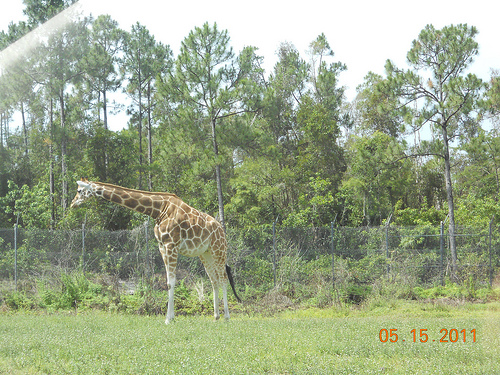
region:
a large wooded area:
[0, 0, 498, 284]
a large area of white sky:
[0, 0, 498, 170]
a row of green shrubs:
[0, 268, 498, 314]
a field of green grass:
[0, 303, 499, 373]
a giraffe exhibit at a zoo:
[0, 0, 499, 374]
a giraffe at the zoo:
[70, 175, 242, 323]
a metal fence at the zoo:
[0, 211, 499, 294]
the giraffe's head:
[70, 175, 95, 208]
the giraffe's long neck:
[92, 180, 170, 219]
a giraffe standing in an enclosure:
[70, 176, 242, 326]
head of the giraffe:
[68, 176, 93, 210]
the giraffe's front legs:
[153, 235, 180, 327]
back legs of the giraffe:
[212, 237, 232, 320]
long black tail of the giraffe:
[222, 254, 248, 304]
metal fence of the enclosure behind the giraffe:
[2, 225, 497, 287]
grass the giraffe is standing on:
[2, 307, 497, 371]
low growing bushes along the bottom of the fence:
[2, 273, 497, 312]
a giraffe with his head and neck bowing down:
[70, 176, 241, 324]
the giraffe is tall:
[77, 137, 334, 344]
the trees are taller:
[150, 14, 485, 281]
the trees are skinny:
[150, 67, 240, 199]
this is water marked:
[325, 307, 460, 374]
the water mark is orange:
[355, 294, 483, 362]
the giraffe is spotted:
[94, 173, 248, 304]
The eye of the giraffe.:
[76, 185, 83, 193]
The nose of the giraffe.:
[72, 200, 82, 208]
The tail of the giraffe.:
[220, 255, 244, 305]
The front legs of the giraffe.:
[156, 245, 183, 322]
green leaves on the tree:
[351, 101, 411, 173]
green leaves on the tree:
[368, 143, 395, 178]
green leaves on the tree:
[220, 158, 265, 215]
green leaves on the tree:
[150, 83, 222, 193]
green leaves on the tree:
[218, 98, 275, 208]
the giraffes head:
[60, 170, 102, 212]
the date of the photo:
[375, 323, 487, 350]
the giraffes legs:
[158, 248, 240, 325]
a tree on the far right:
[396, 30, 488, 297]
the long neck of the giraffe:
[96, 180, 158, 217]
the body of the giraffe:
[162, 208, 221, 258]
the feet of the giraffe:
[165, 309, 232, 327]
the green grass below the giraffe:
[8, 291, 486, 373]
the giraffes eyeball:
[75, 189, 82, 194]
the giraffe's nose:
[68, 198, 75, 211]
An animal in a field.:
[55, 153, 240, 348]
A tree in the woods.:
[186, 2, 257, 338]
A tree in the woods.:
[301, 52, 350, 339]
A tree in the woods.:
[348, 114, 404, 301]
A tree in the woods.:
[347, 64, 456, 319]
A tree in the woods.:
[122, 23, 143, 265]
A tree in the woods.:
[134, 25, 179, 236]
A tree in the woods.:
[78, 16, 140, 288]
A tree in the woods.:
[42, 4, 102, 276]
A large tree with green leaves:
[177, 22, 244, 199]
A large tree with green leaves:
[404, 12, 483, 242]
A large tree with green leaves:
[80, 18, 135, 187]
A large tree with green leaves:
[352, 123, 414, 230]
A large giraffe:
[59, 170, 268, 326]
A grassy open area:
[12, 294, 498, 362]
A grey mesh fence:
[4, 221, 481, 304]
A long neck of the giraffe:
[100, 185, 170, 232]